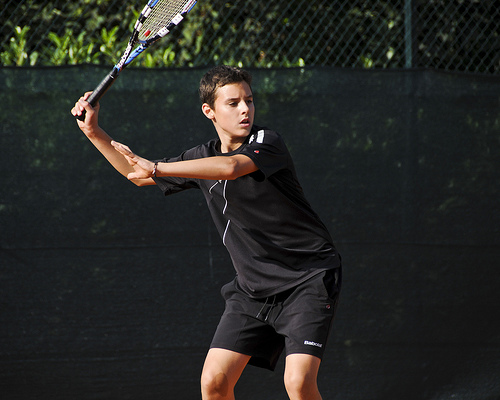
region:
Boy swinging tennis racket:
[69, 2, 346, 399]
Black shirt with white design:
[153, 128, 347, 288]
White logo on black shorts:
[300, 335, 322, 351]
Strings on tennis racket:
[131, 0, 191, 47]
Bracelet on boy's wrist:
[151, 157, 160, 176]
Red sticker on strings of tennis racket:
[141, 27, 151, 37]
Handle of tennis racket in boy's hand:
[63, 92, 100, 123]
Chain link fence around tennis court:
[4, 4, 499, 72]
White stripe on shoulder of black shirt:
[247, 129, 267, 141]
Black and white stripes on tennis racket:
[148, 0, 198, 45]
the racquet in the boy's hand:
[74, 0, 197, 120]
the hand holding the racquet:
[70, 90, 99, 130]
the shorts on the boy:
[210, 254, 341, 358]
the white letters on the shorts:
[302, 339, 322, 348]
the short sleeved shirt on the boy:
[147, 129, 342, 297]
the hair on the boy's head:
[197, 64, 254, 111]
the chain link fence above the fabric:
[0, 2, 498, 69]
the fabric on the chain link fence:
[0, 64, 499, 399]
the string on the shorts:
[255, 296, 277, 322]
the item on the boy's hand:
[151, 159, 158, 179]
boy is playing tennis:
[36, 0, 368, 399]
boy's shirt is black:
[151, 135, 363, 298]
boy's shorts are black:
[182, 276, 354, 366]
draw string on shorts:
[247, 290, 277, 334]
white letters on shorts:
[289, 333, 327, 355]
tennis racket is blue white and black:
[82, 0, 204, 98]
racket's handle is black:
[64, 51, 129, 128]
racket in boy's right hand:
[38, 2, 199, 194]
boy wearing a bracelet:
[142, 150, 164, 184]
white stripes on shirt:
[239, 130, 271, 152]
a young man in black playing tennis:
[73, 49, 365, 399]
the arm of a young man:
[108, 137, 265, 192]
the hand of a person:
[106, 134, 151, 185]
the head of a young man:
[194, 62, 257, 139]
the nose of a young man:
[236, 99, 251, 114]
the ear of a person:
[196, 99, 216, 121]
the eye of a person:
[224, 96, 241, 110]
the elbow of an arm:
[209, 152, 252, 182]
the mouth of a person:
[234, 116, 254, 128]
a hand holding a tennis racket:
[64, 6, 184, 135]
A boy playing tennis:
[65, 2, 348, 398]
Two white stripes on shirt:
[239, 127, 271, 152]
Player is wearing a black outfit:
[142, 59, 346, 374]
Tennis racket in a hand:
[61, 2, 202, 132]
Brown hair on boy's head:
[192, 59, 258, 142]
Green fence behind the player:
[2, 2, 499, 83]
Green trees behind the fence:
[1, 0, 497, 77]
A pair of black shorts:
[208, 264, 345, 371]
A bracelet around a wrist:
[139, 152, 172, 186]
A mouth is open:
[234, 111, 253, 132]